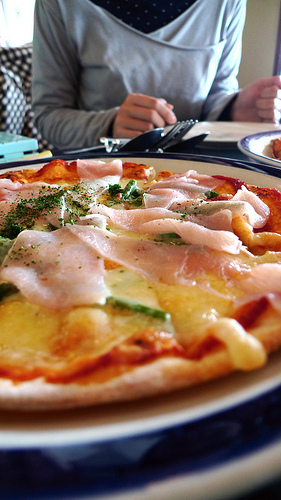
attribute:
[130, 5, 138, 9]
dot — white, black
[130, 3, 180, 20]
shirt — black, grey, gray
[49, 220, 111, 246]
ham — pink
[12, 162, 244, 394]
pizza — here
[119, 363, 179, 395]
crust — brown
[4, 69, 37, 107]
sofa — black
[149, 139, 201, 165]
plate — round, shaded, white, blue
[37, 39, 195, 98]
sweater — grey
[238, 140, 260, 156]
bowl — blue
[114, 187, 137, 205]
broccoli — green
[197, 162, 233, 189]
dish — blue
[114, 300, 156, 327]
herbs — green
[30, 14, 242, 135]
woman — sitting